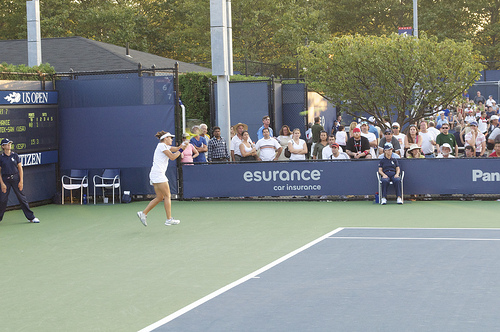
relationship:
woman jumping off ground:
[136, 121, 188, 233] [87, 226, 226, 299]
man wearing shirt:
[1, 136, 46, 220] [2, 148, 27, 175]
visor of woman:
[158, 126, 178, 144] [135, 129, 189, 227]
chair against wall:
[55, 160, 93, 208] [51, 70, 184, 202]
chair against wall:
[91, 161, 124, 208] [51, 70, 184, 202]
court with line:
[2, 201, 499, 329] [133, 224, 347, 330]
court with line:
[2, 201, 499, 329] [329, 233, 498, 249]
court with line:
[2, 201, 499, 329] [340, 216, 498, 236]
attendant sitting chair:
[379, 142, 406, 204] [374, 171, 407, 204]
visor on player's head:
[159, 132, 175, 141] [152, 124, 174, 144]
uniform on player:
[147, 131, 179, 186] [132, 129, 185, 224]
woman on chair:
[377, 142, 403, 204] [375, 167, 404, 204]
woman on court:
[377, 142, 403, 204] [2, 201, 499, 329]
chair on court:
[375, 167, 404, 204] [2, 201, 499, 329]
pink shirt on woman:
[179, 142, 196, 165] [178, 133, 199, 164]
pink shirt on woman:
[181, 142, 196, 160] [178, 133, 199, 164]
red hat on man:
[352, 128, 360, 133] [345, 128, 372, 160]